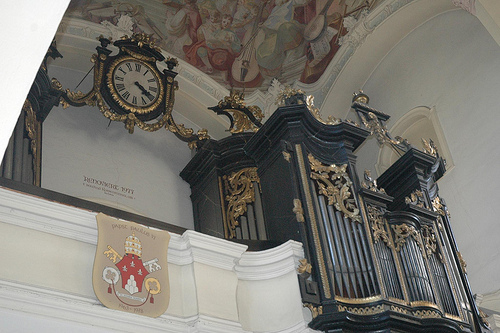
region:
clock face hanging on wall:
[100, 44, 170, 124]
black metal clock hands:
[130, 78, 152, 101]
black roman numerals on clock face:
[108, 58, 136, 108]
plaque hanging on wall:
[79, 204, 188, 324]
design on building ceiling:
[202, 0, 310, 57]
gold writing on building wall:
[76, 169, 148, 204]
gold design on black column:
[305, 154, 364, 234]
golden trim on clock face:
[96, 56, 118, 103]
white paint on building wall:
[424, 22, 471, 92]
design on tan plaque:
[104, 232, 166, 309]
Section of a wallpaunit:
[204, 143, 256, 268]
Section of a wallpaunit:
[291, 198, 363, 310]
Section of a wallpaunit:
[371, 201, 456, 331]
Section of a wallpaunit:
[398, 150, 459, 307]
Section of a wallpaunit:
[254, 140, 353, 258]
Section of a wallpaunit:
[181, 120, 316, 260]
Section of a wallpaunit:
[260, 202, 407, 308]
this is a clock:
[104, 57, 168, 122]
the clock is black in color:
[96, 57, 170, 107]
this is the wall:
[20, 210, 87, 307]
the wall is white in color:
[201, 256, 286, 320]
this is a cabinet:
[347, 209, 439, 309]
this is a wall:
[404, 20, 476, 90]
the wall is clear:
[402, 18, 486, 100]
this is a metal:
[167, 117, 196, 142]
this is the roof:
[243, 8, 328, 70]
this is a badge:
[89, 230, 166, 314]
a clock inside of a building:
[75, 31, 183, 131]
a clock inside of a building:
[40, 25, 245, 166]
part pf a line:
[248, 255, 278, 287]